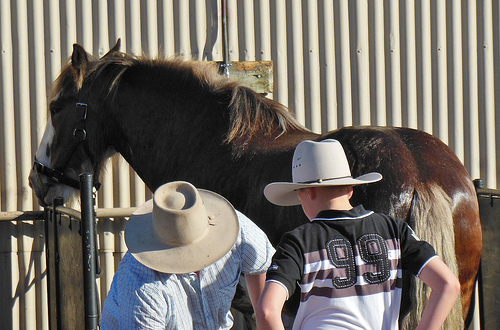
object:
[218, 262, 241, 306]
pocket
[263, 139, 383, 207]
hat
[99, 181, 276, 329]
man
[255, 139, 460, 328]
boy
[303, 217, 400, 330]
back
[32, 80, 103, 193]
bridle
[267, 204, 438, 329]
clothing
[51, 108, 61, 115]
eye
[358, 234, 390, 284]
number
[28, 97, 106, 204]
face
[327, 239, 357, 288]
number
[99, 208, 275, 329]
shirt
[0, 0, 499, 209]
metal wall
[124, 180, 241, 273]
cowboy hat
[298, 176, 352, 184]
black felt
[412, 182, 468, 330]
tail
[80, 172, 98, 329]
post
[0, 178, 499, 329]
pen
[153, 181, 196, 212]
indent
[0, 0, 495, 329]
background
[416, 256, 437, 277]
stripe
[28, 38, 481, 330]
horse